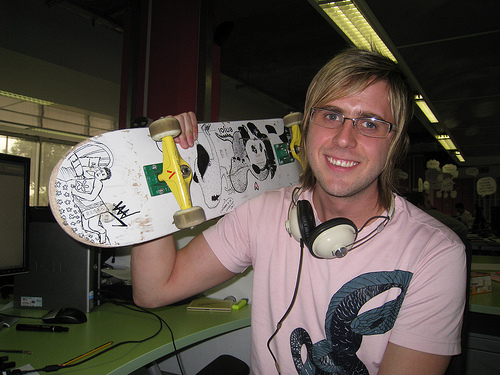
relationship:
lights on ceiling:
[308, 2, 402, 61] [268, 5, 499, 79]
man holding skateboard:
[294, 80, 441, 363] [49, 140, 277, 226]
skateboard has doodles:
[49, 140, 277, 226] [203, 138, 286, 194]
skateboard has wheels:
[49, 140, 277, 226] [154, 119, 202, 231]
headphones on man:
[279, 193, 368, 259] [294, 80, 441, 363]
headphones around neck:
[279, 193, 368, 259] [306, 192, 393, 223]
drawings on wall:
[420, 165, 459, 194] [409, 140, 498, 215]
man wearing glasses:
[294, 80, 441, 363] [320, 102, 398, 144]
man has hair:
[294, 80, 441, 363] [307, 48, 404, 84]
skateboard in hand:
[49, 140, 277, 226] [167, 108, 199, 146]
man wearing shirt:
[294, 80, 441, 363] [237, 228, 436, 362]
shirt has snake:
[237, 228, 436, 362] [326, 273, 392, 373]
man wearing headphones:
[294, 80, 441, 363] [279, 193, 368, 259]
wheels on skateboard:
[154, 119, 202, 231] [49, 140, 277, 226]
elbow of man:
[128, 272, 206, 318] [294, 80, 441, 363]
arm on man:
[102, 244, 253, 304] [294, 80, 441, 363]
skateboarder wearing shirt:
[286, 62, 448, 267] [237, 228, 436, 362]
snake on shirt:
[326, 273, 392, 373] [237, 228, 436, 362]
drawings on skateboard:
[74, 163, 175, 240] [49, 140, 277, 226]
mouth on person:
[325, 147, 372, 175] [294, 80, 441, 363]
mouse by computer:
[33, 302, 90, 327] [1, 157, 113, 342]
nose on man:
[329, 131, 361, 149] [130, 49, 466, 375]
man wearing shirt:
[130, 49, 466, 375] [237, 228, 436, 362]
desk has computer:
[10, 298, 241, 366] [1, 157, 113, 342]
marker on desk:
[14, 319, 72, 342] [10, 298, 241, 366]